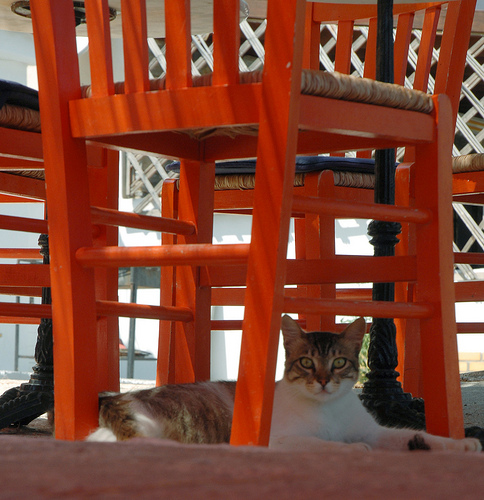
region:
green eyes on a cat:
[299, 349, 351, 374]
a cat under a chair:
[90, 317, 470, 468]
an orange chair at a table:
[29, 1, 478, 437]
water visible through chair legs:
[118, 356, 162, 379]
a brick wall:
[457, 348, 482, 372]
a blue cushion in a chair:
[162, 141, 415, 179]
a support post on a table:
[356, 1, 433, 430]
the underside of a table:
[2, 2, 253, 40]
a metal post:
[125, 260, 147, 376]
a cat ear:
[346, 315, 375, 353]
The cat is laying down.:
[77, 295, 482, 470]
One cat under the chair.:
[44, 92, 483, 457]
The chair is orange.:
[26, 1, 469, 465]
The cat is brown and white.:
[80, 304, 482, 460]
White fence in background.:
[121, 14, 479, 285]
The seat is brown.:
[64, 49, 437, 120]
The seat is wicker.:
[74, 57, 434, 117]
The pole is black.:
[358, 0, 428, 433]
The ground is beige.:
[2, 421, 480, 497]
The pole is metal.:
[356, 129, 432, 436]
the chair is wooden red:
[245, 376, 260, 396]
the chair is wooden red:
[435, 316, 442, 340]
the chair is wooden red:
[64, 351, 86, 394]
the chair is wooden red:
[250, 397, 258, 410]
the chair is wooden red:
[250, 325, 260, 339]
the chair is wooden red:
[419, 270, 434, 298]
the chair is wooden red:
[392, 275, 412, 317]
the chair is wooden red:
[236, 340, 251, 363]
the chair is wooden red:
[435, 327, 446, 367]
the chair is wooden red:
[439, 306, 453, 355]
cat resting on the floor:
[76, 311, 481, 459]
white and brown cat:
[75, 311, 482, 476]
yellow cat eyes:
[290, 347, 357, 385]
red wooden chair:
[22, 4, 481, 270]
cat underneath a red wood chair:
[34, 30, 449, 461]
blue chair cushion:
[158, 147, 420, 234]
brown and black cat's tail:
[91, 385, 171, 450]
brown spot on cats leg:
[384, 416, 464, 461]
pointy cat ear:
[337, 311, 376, 371]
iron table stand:
[6, 346, 55, 443]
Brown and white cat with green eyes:
[94, 312, 445, 450]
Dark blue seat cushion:
[159, 152, 394, 174]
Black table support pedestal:
[367, 0, 438, 429]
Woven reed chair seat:
[57, 70, 442, 110]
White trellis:
[126, 147, 161, 211]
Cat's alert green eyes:
[296, 355, 352, 371]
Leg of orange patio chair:
[401, 142, 469, 442]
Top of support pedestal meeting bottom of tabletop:
[14, 0, 121, 26]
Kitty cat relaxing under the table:
[98, 312, 478, 450]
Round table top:
[3, 0, 248, 35]